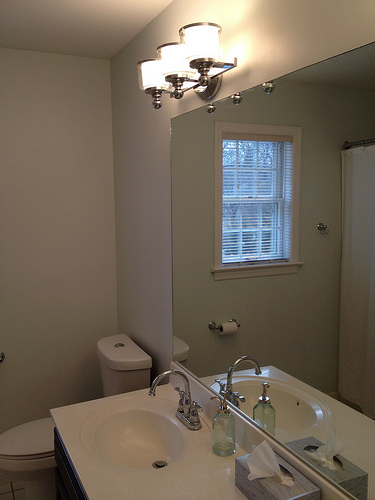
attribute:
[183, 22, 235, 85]
light — on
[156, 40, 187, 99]
light — on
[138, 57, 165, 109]
light — on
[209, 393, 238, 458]
bottle — green, glass, empty, almost empty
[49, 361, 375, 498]
sink — white, clean, porceline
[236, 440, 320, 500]
tissue box — gray, grey, open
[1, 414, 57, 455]
toilet seat — down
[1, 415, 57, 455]
toilet cover — down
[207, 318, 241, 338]
toilet paper — rolled, reflected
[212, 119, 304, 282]
window — closed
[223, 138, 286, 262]
mini blinds — open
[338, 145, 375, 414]
shower curtain — white, hanging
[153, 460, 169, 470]
sink drain — silver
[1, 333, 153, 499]
toilet — white, large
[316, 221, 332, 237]
wall hook — silver, metal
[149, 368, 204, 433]
faucet — silver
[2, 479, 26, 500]
tile — white